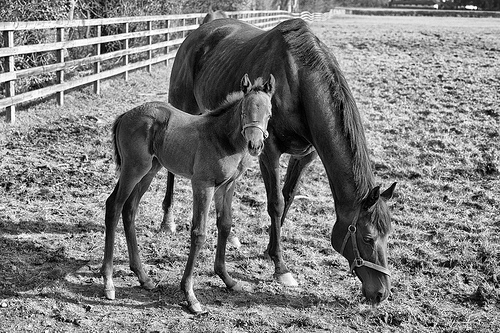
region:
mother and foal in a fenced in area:
[5, 3, 492, 327]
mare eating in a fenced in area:
[171, 11, 398, 305]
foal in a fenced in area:
[98, 73, 275, 316]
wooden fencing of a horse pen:
[2, 3, 310, 127]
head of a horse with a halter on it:
[327, 204, 400, 304]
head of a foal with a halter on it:
[237, 73, 276, 153]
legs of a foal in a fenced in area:
[86, 154, 238, 311]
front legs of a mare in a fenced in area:
[257, 146, 314, 288]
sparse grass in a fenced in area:
[343, 0, 492, 262]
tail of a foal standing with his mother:
[110, 111, 125, 171]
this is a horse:
[89, 64, 281, 324]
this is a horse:
[159, 2, 414, 329]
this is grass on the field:
[404, 215, 468, 288]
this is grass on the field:
[379, 130, 472, 239]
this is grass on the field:
[445, 41, 490, 118]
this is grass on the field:
[24, 129, 83, 212]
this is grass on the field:
[355, 36, 421, 139]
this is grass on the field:
[412, 67, 487, 160]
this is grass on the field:
[359, 2, 459, 109]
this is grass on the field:
[238, 221, 335, 327]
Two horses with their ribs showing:
[99, 11, 399, 315]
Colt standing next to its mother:
[96, 8, 393, 312]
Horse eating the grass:
[158, 8, 395, 303]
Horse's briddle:
[337, 195, 394, 277]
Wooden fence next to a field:
[2, 3, 347, 125]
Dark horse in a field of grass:
[168, 9, 397, 306]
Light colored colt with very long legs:
[97, 73, 279, 313]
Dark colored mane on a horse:
[287, 20, 390, 231]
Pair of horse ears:
[237, 72, 279, 93]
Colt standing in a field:
[94, 72, 277, 312]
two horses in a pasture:
[83, 0, 479, 323]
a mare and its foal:
[76, 0, 406, 322]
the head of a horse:
[327, 179, 405, 306]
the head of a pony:
[237, 72, 279, 164]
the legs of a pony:
[99, 172, 254, 320]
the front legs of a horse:
[260, 158, 314, 291]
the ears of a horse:
[362, 176, 399, 210]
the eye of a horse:
[361, 230, 376, 247]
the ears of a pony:
[236, 68, 278, 94]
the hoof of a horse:
[271, 268, 301, 293]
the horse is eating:
[312, 170, 412, 327]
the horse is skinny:
[81, 55, 302, 330]